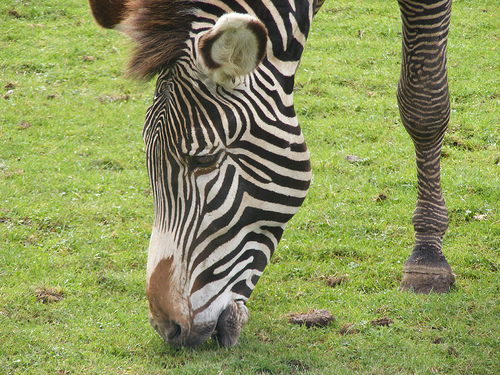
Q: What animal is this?
A: Zebra.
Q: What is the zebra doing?
A: Grazing.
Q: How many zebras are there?
A: One.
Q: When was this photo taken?
A: During the day.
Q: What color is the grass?
A: Green.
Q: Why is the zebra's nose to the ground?
A: Eat grass.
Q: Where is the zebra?
A: Outside in a field.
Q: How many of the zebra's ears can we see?
A: Two.